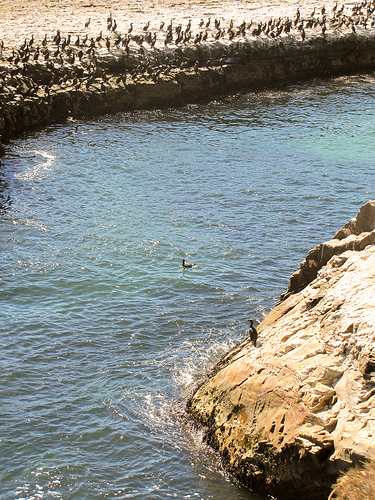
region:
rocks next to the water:
[180, 187, 363, 497]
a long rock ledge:
[16, 0, 361, 126]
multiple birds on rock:
[20, 1, 370, 115]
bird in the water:
[165, 240, 218, 279]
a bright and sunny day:
[10, 8, 372, 499]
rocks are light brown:
[164, 270, 374, 481]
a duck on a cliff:
[241, 317, 264, 348]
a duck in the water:
[168, 253, 201, 278]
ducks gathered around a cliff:
[0, 8, 373, 108]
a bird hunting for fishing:
[164, 245, 207, 280]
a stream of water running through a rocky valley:
[2, 69, 367, 483]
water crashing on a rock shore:
[153, 335, 243, 472]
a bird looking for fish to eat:
[209, 308, 262, 359]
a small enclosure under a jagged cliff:
[176, 50, 372, 101]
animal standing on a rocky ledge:
[243, 314, 262, 346]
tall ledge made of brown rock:
[180, 198, 372, 499]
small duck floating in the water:
[176, 253, 195, 270]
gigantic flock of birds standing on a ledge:
[0, 0, 374, 120]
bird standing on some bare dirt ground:
[196, 13, 207, 30]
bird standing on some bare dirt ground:
[73, 34, 81, 46]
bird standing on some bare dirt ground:
[125, 19, 136, 35]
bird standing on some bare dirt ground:
[81, 14, 93, 30]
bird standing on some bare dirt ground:
[306, 4, 318, 17]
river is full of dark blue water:
[0, 69, 374, 497]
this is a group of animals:
[30, 26, 237, 77]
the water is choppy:
[75, 218, 187, 355]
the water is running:
[64, 238, 200, 350]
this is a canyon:
[28, 124, 262, 317]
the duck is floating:
[159, 236, 224, 300]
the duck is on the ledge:
[223, 305, 285, 344]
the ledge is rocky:
[222, 353, 318, 421]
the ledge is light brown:
[219, 358, 367, 441]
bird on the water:
[174, 252, 203, 275]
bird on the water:
[174, 251, 205, 286]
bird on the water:
[168, 250, 203, 281]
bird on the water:
[173, 249, 199, 275]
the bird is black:
[236, 312, 264, 345]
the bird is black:
[236, 308, 263, 348]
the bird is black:
[236, 310, 269, 359]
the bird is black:
[241, 305, 274, 345]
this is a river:
[17, 77, 372, 373]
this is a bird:
[229, 302, 267, 371]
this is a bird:
[175, 253, 193, 279]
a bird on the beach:
[38, 25, 55, 44]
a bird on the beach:
[295, 17, 308, 41]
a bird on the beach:
[281, 15, 294, 35]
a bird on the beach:
[307, 4, 315, 17]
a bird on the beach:
[74, 74, 82, 83]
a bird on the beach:
[34, 44, 49, 67]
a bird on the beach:
[129, 68, 141, 84]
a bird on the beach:
[176, 26, 188, 42]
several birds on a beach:
[10, 11, 371, 73]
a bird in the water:
[181, 253, 200, 277]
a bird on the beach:
[80, 15, 91, 27]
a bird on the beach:
[140, 19, 148, 31]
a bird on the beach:
[169, 22, 188, 38]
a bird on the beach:
[215, 28, 218, 35]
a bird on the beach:
[229, 16, 235, 29]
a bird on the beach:
[192, 30, 202, 41]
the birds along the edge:
[18, 5, 364, 54]